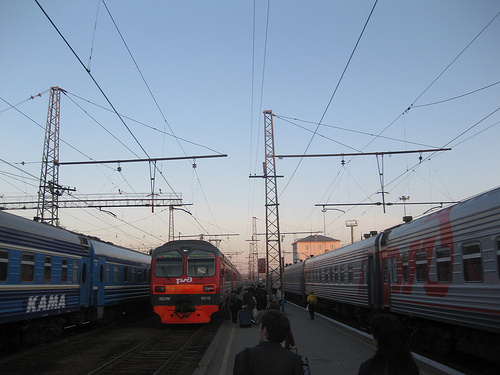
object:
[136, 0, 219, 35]
white clouds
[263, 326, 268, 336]
ear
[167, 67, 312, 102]
clouds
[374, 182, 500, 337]
passenger car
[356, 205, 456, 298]
red letters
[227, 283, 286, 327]
crowd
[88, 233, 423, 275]
sunset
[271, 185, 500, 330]
train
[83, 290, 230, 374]
rail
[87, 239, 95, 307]
compartment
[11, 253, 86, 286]
windows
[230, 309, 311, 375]
man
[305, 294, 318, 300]
shirt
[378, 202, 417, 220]
clouds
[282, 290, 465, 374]
tracks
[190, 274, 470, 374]
walkway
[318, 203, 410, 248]
cloud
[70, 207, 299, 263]
cloud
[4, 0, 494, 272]
sky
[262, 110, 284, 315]
rail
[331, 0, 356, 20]
white clouds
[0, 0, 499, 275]
blue sky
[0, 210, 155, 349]
blue train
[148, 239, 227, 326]
engine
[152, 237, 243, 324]
train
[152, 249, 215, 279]
glass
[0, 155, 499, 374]
railway station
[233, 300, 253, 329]
people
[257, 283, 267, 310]
people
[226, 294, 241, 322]
people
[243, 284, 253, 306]
people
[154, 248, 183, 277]
windshield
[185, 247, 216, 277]
windshield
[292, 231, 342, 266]
building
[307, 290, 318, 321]
man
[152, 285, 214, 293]
headlight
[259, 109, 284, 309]
electric pole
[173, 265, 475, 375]
platform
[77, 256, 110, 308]
doors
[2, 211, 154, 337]
train cars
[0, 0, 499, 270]
electric cables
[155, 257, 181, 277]
window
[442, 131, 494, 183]
clouds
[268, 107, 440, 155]
cables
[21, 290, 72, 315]
kama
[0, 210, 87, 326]
side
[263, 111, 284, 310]
tower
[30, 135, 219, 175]
clouds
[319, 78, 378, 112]
clouds